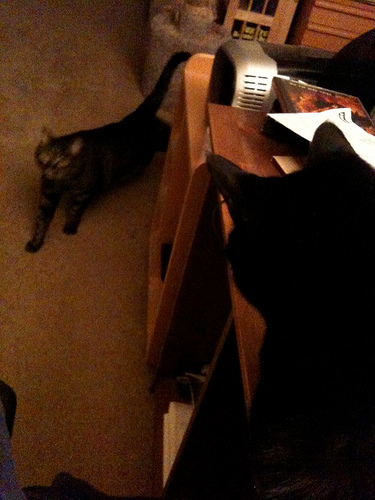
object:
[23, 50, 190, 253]
cat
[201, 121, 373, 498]
cat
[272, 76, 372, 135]
printer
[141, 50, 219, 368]
stand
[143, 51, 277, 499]
furniture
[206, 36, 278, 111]
dvd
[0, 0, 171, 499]
carpet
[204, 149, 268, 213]
ears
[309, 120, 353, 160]
ears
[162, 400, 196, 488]
documents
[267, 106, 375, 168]
letter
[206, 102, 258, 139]
ege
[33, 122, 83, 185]
face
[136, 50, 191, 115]
tail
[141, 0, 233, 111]
post